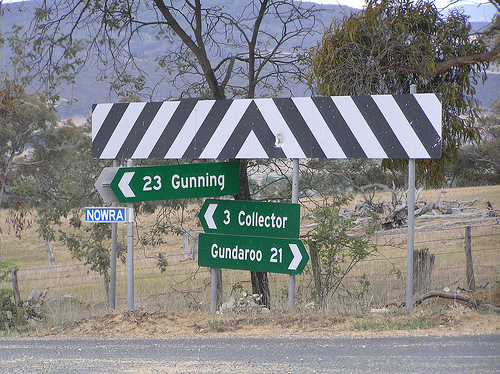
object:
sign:
[197, 232, 309, 275]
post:
[287, 272, 295, 303]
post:
[211, 265, 218, 316]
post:
[125, 203, 135, 310]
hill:
[0, 187, 500, 299]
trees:
[299, 3, 492, 187]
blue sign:
[85, 207, 125, 221]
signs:
[109, 165, 311, 285]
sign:
[88, 93, 443, 159]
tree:
[13, 0, 488, 312]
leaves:
[2, 2, 499, 187]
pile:
[305, 178, 500, 227]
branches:
[339, 170, 488, 228]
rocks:
[216, 291, 270, 315]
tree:
[290, 1, 494, 188]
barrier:
[90, 97, 438, 313]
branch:
[306, 176, 496, 231]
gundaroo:
[198, 233, 311, 275]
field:
[1, 182, 497, 333]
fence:
[0, 222, 498, 313]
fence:
[314, 232, 409, 303]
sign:
[198, 199, 310, 276]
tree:
[283, 25, 462, 175]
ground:
[0, 185, 500, 325]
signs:
[194, 199, 314, 277]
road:
[1, 339, 499, 373]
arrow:
[287, 243, 304, 271]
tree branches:
[343, 181, 475, 234]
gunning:
[171, 173, 226, 190]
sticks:
[355, 180, 478, 226]